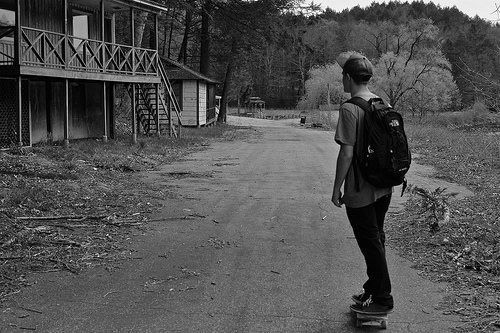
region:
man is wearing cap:
[335, 41, 390, 86]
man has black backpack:
[342, 87, 392, 182]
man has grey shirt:
[322, 87, 387, 221]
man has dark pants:
[365, 183, 409, 328]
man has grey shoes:
[350, 277, 405, 328]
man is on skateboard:
[340, 274, 384, 328]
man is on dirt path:
[288, 58, 425, 316]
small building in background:
[141, 54, 225, 139]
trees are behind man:
[280, 45, 497, 93]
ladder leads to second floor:
[130, 47, 198, 131]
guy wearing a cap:
[330, 46, 425, 331]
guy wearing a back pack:
[313, 51, 428, 331]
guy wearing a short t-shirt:
[300, 57, 421, 330]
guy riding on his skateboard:
[292, 40, 434, 331]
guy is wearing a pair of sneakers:
[300, 44, 427, 331]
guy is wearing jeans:
[303, 49, 434, 331]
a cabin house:
[0, 2, 227, 151]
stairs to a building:
[113, 46, 192, 136]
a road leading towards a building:
[22, 99, 479, 331]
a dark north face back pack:
[345, 92, 418, 193]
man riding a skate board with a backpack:
[330, 48, 409, 327]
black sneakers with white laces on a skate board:
[348, 284, 395, 317]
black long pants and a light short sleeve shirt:
[324, 92, 394, 297]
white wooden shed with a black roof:
[138, 59, 213, 134]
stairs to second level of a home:
[126, 52, 184, 138]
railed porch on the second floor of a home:
[3, 0, 167, 92]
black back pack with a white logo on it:
[344, 91, 411, 189]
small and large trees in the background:
[179, 2, 493, 113]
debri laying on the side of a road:
[11, 194, 108, 274]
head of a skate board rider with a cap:
[331, 48, 379, 94]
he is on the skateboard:
[346, 285, 391, 323]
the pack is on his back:
[345, 95, 408, 158]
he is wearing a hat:
[333, 43, 378, 86]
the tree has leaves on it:
[251, 14, 281, 47]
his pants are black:
[356, 224, 378, 251]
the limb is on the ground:
[20, 210, 105, 225]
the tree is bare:
[454, 56, 497, 103]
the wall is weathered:
[72, 90, 98, 119]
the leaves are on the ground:
[438, 154, 473, 180]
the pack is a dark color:
[371, 123, 394, 157]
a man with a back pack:
[317, 26, 405, 223]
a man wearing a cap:
[337, 40, 379, 100]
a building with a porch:
[3, 0, 216, 174]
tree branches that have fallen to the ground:
[13, 171, 169, 288]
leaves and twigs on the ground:
[460, 126, 487, 296]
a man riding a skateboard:
[328, 47, 408, 332]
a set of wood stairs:
[104, 56, 175, 150]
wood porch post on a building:
[11, 12, 159, 62]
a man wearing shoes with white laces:
[345, 281, 398, 326]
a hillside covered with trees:
[263, 6, 493, 65]